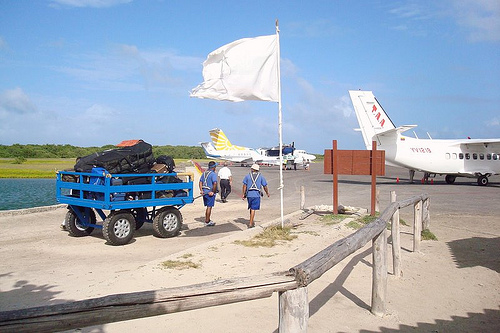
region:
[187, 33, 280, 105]
white flag flapping in the wind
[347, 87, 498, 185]
white and red plane on runway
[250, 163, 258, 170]
man wearing a white hat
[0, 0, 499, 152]
sky is bright blue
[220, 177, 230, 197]
man wearing black pants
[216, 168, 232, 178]
man wearing a white shirt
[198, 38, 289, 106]
white flag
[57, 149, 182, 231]
blue luggage cart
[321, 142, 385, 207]
wooden brown sign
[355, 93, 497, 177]
white plane on ground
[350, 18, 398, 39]
white clouds in blue sky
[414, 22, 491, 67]
white clouds in blue sky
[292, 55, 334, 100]
white clouds in blue sky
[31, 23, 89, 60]
white clouds in blue sky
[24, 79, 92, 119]
white clouds in blue sky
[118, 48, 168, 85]
white clouds in blue sky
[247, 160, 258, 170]
White hat on a man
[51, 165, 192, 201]
Blue trailer behind men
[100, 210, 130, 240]
Back tire on trailer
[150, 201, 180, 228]
Front tire on a trailer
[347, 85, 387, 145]
Tail of a jet plane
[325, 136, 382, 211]
A brown sign on the ground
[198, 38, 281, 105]
A white flag on a pole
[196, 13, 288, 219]
A pole with a white flag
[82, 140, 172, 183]
Luggage in a blue trailer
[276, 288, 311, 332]
Wooden fence post on ground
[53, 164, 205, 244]
medium blue cargo wagon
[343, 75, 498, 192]
back and side of white plane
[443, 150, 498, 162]
row of windows on plane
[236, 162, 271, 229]
person in white hat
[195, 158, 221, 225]
man in blue shorts pulling wagon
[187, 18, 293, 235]
waving white flag on pole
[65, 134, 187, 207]
pile of travel bags in wagon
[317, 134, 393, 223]
back of brown wooden sign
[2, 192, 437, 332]
wood post fence rail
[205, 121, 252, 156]
yellow tail of airplane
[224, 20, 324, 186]
a flag on a pole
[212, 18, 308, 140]
flag on a metal pole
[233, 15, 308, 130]
pole with a flag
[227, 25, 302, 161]
metal pole with a flag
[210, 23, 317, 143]
white flag on pole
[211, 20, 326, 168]
white flag on a metal pole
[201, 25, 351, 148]
pole with a white flag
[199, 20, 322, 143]
metal pole with a white flag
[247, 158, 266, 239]
a person walking outside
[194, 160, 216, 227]
a person walking outside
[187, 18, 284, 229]
A pole with white flag on it.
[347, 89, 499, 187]
A white airplane with red words.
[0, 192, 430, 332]
A wooden fence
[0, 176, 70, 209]
A lake with green water.